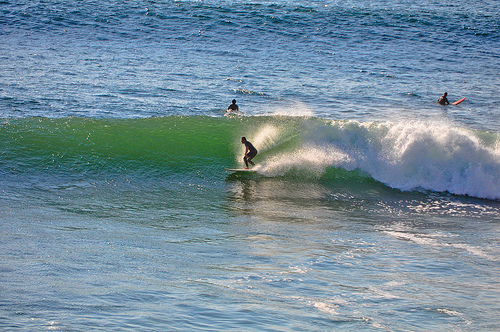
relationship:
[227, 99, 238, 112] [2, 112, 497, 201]
man behind wave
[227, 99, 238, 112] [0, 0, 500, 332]
man surfing ground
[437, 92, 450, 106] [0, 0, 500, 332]
man surfing ground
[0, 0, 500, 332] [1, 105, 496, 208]
ground in wave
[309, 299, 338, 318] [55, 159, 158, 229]
foam on water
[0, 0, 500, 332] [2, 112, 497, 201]
ground behind wave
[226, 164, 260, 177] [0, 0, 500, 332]
surfboard in ground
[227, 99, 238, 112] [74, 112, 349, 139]
man behind wave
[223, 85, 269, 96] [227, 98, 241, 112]
wave behind man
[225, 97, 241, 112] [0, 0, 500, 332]
man in ground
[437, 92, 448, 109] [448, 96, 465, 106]
man with surfboard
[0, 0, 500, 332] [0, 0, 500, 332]
ground in ground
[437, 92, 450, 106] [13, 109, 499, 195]
man waiting for wave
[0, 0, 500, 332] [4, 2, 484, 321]
ground in ocean water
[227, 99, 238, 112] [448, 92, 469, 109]
man riding on surfboard